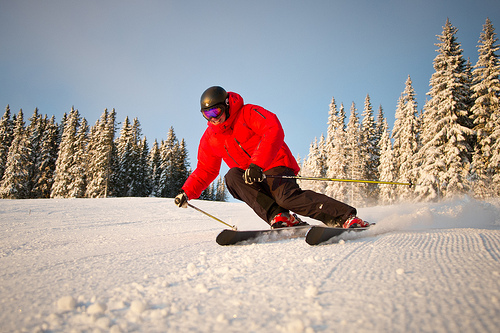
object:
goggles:
[201, 103, 225, 120]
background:
[0, 0, 500, 333]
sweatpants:
[222, 164, 358, 226]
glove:
[241, 162, 267, 187]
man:
[174, 85, 374, 229]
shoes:
[330, 206, 368, 229]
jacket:
[180, 91, 300, 201]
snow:
[2, 24, 499, 195]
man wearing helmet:
[147, 82, 379, 249]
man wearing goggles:
[171, 85, 393, 247]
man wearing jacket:
[158, 85, 380, 266]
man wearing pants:
[167, 83, 378, 251]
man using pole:
[166, 78, 371, 263]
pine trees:
[84, 101, 119, 198]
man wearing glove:
[154, 85, 372, 250]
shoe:
[264, 205, 310, 228]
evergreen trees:
[417, 16, 474, 200]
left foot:
[267, 209, 308, 229]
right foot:
[333, 212, 375, 228]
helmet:
[200, 85, 231, 109]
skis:
[215, 219, 309, 247]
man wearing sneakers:
[158, 72, 381, 250]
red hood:
[226, 90, 246, 124]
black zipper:
[232, 136, 253, 159]